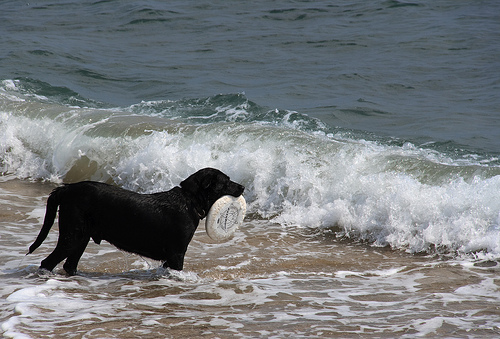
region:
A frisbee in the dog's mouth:
[206, 193, 245, 243]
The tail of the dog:
[29, 189, 58, 252]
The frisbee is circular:
[206, 193, 244, 238]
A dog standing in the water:
[27, 167, 244, 275]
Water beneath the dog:
[0, 1, 497, 338]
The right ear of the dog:
[201, 172, 214, 189]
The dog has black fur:
[28, 168, 243, 273]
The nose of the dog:
[238, 182, 244, 191]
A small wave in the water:
[1, 86, 498, 256]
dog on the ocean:
[49, 178, 226, 278]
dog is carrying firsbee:
[205, 170, 263, 241]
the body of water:
[307, 26, 428, 101]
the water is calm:
[200, 19, 337, 84]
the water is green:
[391, 30, 468, 114]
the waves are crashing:
[332, 154, 442, 246]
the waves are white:
[422, 179, 499, 242]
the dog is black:
[99, 205, 165, 242]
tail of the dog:
[15, 189, 57, 265]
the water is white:
[363, 177, 439, 237]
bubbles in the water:
[293, 270, 398, 331]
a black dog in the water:
[28, 167, 243, 280]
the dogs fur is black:
[85, 189, 155, 230]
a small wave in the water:
[294, 148, 385, 206]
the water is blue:
[355, 38, 451, 116]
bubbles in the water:
[305, 272, 460, 330]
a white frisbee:
[208, 197, 247, 242]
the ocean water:
[153, 18, 270, 65]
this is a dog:
[29, 161, 250, 281]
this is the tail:
[23, 196, 60, 253]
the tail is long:
[22, 194, 57, 251]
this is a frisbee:
[204, 193, 246, 242]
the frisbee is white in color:
[202, 195, 247, 239]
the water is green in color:
[334, 33, 446, 104]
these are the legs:
[47, 237, 89, 274]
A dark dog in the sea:
[29, 165, 249, 277]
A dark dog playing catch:
[24, 165, 246, 275]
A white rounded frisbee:
[207, 190, 247, 241]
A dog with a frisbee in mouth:
[25, 164, 252, 281]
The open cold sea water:
[0, 0, 499, 337]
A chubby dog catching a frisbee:
[30, 168, 247, 273]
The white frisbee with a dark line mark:
[208, 193, 245, 240]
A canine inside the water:
[22, 165, 249, 283]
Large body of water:
[245, 38, 364, 108]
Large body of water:
[366, 20, 461, 137]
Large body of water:
[276, 28, 405, 117]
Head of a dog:
[186, 162, 248, 203]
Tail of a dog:
[23, 183, 60, 255]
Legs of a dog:
[28, 232, 85, 277]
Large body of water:
[282, 14, 419, 115]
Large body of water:
[373, 42, 473, 144]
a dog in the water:
[76, 111, 309, 332]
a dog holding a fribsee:
[191, 174, 245, 246]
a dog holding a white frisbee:
[186, 154, 257, 254]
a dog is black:
[48, 141, 322, 333]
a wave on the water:
[266, 93, 436, 248]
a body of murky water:
[358, 58, 488, 211]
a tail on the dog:
[11, 172, 74, 244]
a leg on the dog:
[51, 232, 59, 262]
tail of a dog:
[27, 186, 60, 249]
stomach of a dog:
[100, 230, 132, 248]